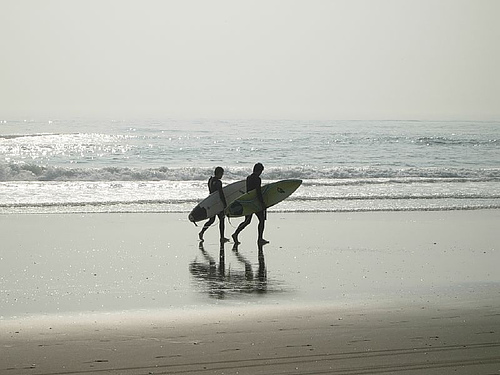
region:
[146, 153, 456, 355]
Two surfers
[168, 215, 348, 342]
reflection of the surfers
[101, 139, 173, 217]
waves on the beach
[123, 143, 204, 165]
ocean behind the surfers.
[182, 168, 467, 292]
carrying two surf boards.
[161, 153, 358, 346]
Two surfers walking down the shore.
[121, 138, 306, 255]
Nice water on the beach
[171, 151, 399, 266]
Two surfboards in the men's hands.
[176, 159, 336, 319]
Looking for waves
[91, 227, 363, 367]
footprints in the sand on the beach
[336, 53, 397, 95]
part of the sky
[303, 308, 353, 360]
part of the beach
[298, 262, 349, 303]
part of a wet part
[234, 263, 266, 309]
part of a shadow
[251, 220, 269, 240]
part of a right leg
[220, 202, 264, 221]
part of a swimming board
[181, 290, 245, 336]
edge of the wet part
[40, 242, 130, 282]
water on the beach.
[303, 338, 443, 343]
sand on the beach.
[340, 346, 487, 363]
tracks in the sand.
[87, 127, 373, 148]
water in the ocean.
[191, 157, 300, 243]
people on the beach.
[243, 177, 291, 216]
surfboard under person's arm.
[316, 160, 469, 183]
waves coming to the shore.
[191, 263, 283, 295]
people's reflection in the water.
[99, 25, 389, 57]
clear sunny sky.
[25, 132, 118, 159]
light reflecting off of the waves.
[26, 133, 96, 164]
sun reflecting off ocean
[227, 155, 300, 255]
man on beach carrying surfboard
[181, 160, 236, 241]
man on beach carrying surfboard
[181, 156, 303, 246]
Two men walking with surfboards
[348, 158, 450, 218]
Waves coming into shore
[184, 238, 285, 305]
reflection of surfers on wet sand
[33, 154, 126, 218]
Small crashing wave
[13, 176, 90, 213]
Foamy ocean waves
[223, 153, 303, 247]
Man with surfboard walking on wet sand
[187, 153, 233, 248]
Surfboard-carrying man walking on reflective sand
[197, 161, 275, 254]
the man and the woman are walking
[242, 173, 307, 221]
the man is carrying a surf board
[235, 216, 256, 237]
the knee is bent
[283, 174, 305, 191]
the surf board has sharp head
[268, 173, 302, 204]
the surf board is white in color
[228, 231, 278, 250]
the man is bare footed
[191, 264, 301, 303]
the sand is wet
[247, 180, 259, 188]
the man is bare chested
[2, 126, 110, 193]
these are waves on the sea